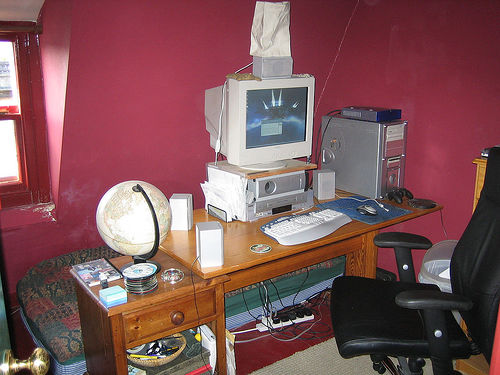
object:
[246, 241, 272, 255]
cd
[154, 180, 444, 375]
desk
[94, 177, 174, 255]
globe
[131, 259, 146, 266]
base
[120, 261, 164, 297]
cds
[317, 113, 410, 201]
computer tower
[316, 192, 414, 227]
mousepad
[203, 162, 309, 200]
soundsystem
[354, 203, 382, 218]
mouse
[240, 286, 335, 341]
cords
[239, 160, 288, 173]
base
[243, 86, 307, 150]
monitor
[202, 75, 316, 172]
computer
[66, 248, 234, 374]
table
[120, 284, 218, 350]
drawer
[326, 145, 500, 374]
desk chair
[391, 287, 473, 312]
handrest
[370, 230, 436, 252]
handrest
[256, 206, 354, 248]
keyboard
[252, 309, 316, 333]
power strip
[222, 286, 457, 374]
floor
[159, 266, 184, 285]
ash tray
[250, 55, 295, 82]
computer speaker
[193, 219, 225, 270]
computer speaker